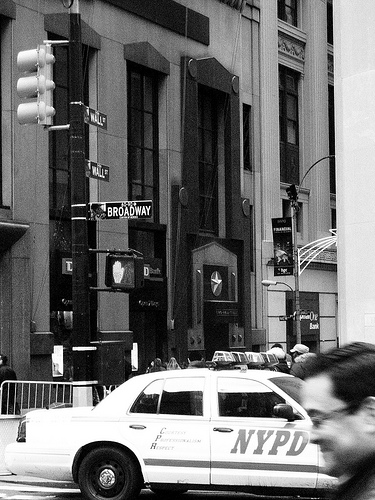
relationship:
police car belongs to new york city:
[4, 347, 338, 497] [1, 0, 374, 497]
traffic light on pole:
[7, 40, 61, 131] [53, 4, 100, 415]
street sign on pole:
[87, 191, 155, 225] [53, 4, 100, 415]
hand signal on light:
[112, 261, 127, 286] [98, 245, 142, 294]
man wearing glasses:
[287, 339, 375, 498] [301, 404, 346, 427]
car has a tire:
[4, 347, 338, 497] [78, 447, 138, 499]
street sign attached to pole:
[87, 191, 155, 225] [53, 4, 100, 415]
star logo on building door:
[208, 267, 223, 299] [187, 228, 247, 352]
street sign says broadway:
[87, 191, 155, 225] [103, 202, 150, 218]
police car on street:
[4, 347, 338, 497] [0, 458, 332, 500]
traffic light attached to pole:
[7, 40, 61, 131] [53, 4, 100, 415]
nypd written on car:
[229, 422, 310, 461] [4, 347, 338, 497]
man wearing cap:
[287, 337, 311, 365] [287, 339, 311, 360]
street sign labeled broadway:
[87, 191, 155, 225] [103, 202, 150, 218]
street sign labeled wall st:
[88, 156, 113, 185] [91, 162, 113, 180]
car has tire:
[4, 347, 338, 497] [78, 447, 138, 499]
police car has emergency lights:
[4, 347, 338, 497] [210, 345, 272, 372]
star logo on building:
[208, 267, 223, 299] [0, 0, 335, 408]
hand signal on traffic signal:
[112, 261, 127, 286] [98, 245, 142, 294]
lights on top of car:
[210, 345, 272, 372] [4, 347, 338, 497]